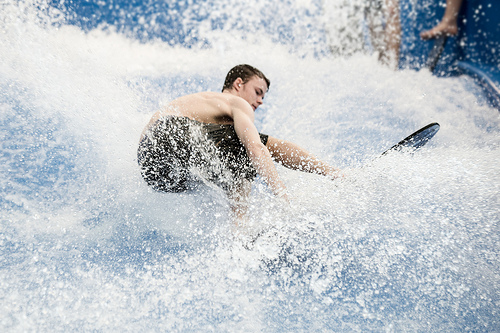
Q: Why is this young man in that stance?
A: Leaning with the waves.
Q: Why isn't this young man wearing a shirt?
A: He is surfing.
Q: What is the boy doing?
A: Surfing.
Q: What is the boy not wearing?
A: Shirt.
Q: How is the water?
A: Rough.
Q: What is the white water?
A: Waves.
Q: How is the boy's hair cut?
A: Short.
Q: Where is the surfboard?
A: Underwater.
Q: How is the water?
A: Blue.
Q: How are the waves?
A: Rough.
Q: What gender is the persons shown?
A: Male.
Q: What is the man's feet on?
A: Surfboard.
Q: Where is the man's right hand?
A: Holding the surfboard?.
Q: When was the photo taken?
A: Daytime.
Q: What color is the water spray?
A: White.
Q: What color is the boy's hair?
A: Brown.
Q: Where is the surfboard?
A: In the water.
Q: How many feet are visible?
A: One.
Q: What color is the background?
A: Blue.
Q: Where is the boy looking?
A: Toward the board.